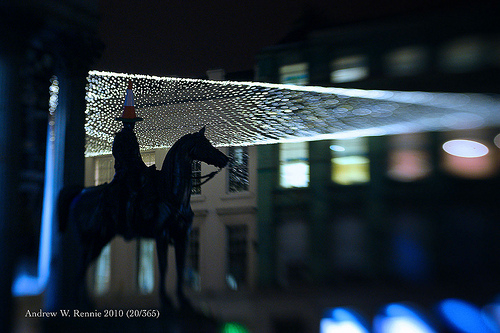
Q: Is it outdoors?
A: Yes, it is outdoors.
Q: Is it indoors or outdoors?
A: It is outdoors.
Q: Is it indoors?
A: No, it is outdoors.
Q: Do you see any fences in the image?
A: No, there are no fences.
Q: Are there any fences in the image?
A: No, there are no fences.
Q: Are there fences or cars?
A: No, there are no fences or cars.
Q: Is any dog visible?
A: No, there are no dogs.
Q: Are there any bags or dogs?
A: No, there are no dogs or bags.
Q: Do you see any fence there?
A: No, there are no fences.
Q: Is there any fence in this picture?
A: No, there are no fences.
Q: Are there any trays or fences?
A: No, there are no fences or trays.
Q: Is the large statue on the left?
A: Yes, the statue is on the left of the image.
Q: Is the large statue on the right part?
A: No, the statue is on the left of the image.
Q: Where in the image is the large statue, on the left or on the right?
A: The statue is on the left of the image.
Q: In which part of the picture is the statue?
A: The statue is on the left of the image.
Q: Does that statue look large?
A: Yes, the statue is large.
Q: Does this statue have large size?
A: Yes, the statue is large.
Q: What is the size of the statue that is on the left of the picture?
A: The statue is large.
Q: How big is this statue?
A: The statue is large.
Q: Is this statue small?
A: No, the statue is large.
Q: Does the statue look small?
A: No, the statue is large.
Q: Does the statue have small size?
A: No, the statue is large.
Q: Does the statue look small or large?
A: The statue is large.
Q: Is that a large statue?
A: Yes, that is a large statue.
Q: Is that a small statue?
A: No, that is a large statue.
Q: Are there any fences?
A: No, there are no fences.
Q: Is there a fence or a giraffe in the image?
A: No, there are no fences or giraffes.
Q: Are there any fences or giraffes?
A: No, there are no fences or giraffes.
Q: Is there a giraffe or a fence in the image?
A: No, there are no fences or giraffes.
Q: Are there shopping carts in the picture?
A: No, there are no shopping carts.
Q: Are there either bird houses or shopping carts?
A: No, there are no shopping carts or bird houses.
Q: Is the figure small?
A: Yes, the figure is small.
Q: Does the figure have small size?
A: Yes, the figure is small.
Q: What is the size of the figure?
A: The figure is small.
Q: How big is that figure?
A: The figure is small.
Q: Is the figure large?
A: No, the figure is small.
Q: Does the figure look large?
A: No, the figure is small.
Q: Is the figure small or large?
A: The figure is small.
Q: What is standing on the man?
A: The figure is standing on the man.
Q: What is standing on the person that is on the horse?
A: The figure is standing on the man.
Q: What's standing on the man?
A: The figure is standing on the man.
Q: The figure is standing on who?
A: The figure is standing on the man.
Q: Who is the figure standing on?
A: The figure is standing on the man.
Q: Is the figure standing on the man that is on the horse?
A: Yes, the figure is standing on the man.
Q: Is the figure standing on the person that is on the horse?
A: Yes, the figure is standing on the man.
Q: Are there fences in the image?
A: No, there are no fences.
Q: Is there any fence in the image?
A: No, there are no fences.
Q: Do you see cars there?
A: No, there are no cars.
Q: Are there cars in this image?
A: No, there are no cars.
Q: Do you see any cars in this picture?
A: No, there are no cars.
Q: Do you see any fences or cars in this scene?
A: No, there are no cars or fences.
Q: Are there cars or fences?
A: No, there are no cars or fences.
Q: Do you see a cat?
A: No, there are no cats.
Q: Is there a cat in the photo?
A: No, there are no cats.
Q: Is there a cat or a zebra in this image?
A: No, there are no cats or zebras.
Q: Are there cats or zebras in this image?
A: No, there are no cats or zebras.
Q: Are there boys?
A: No, there are no boys.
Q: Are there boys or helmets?
A: No, there are no boys or helmets.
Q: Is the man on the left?
A: Yes, the man is on the left of the image.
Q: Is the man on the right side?
A: No, the man is on the left of the image.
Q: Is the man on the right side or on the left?
A: The man is on the left of the image.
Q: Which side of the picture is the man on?
A: The man is on the left of the image.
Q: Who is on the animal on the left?
A: The man is on the horse.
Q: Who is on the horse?
A: The man is on the horse.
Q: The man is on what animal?
A: The man is on the horse.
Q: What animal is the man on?
A: The man is on the horse.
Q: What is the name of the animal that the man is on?
A: The animal is a horse.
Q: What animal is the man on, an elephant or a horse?
A: The man is on a horse.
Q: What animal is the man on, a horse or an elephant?
A: The man is on a horse.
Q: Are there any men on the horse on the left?
A: Yes, there is a man on the horse.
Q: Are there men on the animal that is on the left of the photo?
A: Yes, there is a man on the horse.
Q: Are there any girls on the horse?
A: No, there is a man on the horse.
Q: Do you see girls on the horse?
A: No, there is a man on the horse.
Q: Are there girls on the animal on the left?
A: No, there is a man on the horse.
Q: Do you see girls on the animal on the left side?
A: No, there is a man on the horse.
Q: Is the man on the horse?
A: Yes, the man is on the horse.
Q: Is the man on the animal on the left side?
A: Yes, the man is on the horse.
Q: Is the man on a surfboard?
A: No, the man is on the horse.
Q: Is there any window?
A: Yes, there is a window.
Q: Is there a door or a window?
A: Yes, there is a window.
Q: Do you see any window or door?
A: Yes, there is a window.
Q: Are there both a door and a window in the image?
A: No, there is a window but no doors.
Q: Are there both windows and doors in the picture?
A: No, there is a window but no doors.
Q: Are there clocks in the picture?
A: No, there are no clocks.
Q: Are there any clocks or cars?
A: No, there are no clocks or cars.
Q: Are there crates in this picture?
A: No, there are no crates.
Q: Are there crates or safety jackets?
A: No, there are no crates or safety jackets.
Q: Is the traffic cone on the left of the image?
A: Yes, the traffic cone is on the left of the image.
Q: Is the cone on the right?
A: No, the cone is on the left of the image.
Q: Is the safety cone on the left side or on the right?
A: The safety cone is on the left of the image.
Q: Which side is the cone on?
A: The cone is on the left of the image.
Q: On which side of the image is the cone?
A: The cone is on the left of the image.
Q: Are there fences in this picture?
A: No, there are no fences.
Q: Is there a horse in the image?
A: Yes, there is a horse.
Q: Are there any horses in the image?
A: Yes, there is a horse.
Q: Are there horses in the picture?
A: Yes, there is a horse.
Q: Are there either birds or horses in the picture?
A: Yes, there is a horse.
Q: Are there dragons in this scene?
A: No, there are no dragons.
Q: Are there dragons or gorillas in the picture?
A: No, there are no dragons or gorillas.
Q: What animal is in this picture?
A: The animal is a horse.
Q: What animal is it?
A: The animal is a horse.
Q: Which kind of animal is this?
A: That is a horse.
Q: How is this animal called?
A: That is a horse.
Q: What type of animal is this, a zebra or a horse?
A: That is a horse.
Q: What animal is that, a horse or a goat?
A: That is a horse.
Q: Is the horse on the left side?
A: Yes, the horse is on the left of the image.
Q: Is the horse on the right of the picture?
A: No, the horse is on the left of the image.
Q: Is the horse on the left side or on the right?
A: The horse is on the left of the image.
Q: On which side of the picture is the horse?
A: The horse is on the left of the image.